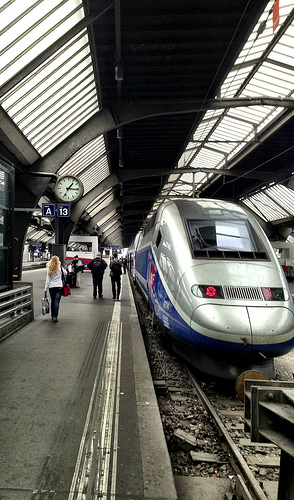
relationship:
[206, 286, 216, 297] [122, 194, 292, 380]
light mounted to train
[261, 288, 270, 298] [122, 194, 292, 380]
light mounted to train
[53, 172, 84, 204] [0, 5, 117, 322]
clock hanging wall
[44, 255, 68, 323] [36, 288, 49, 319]
passengers carrying luggage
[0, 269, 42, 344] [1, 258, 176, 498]
railing next to walkway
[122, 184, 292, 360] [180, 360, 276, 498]
train on tracks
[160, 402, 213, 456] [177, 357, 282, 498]
debris on tracks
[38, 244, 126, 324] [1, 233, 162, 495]
passengers on platform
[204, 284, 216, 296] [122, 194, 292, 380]
light on train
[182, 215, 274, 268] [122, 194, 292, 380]
windshield on train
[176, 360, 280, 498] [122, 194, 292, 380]
track in front of train